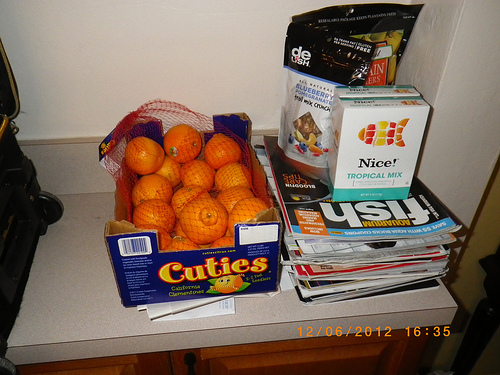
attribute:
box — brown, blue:
[101, 214, 289, 309]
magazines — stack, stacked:
[291, 191, 437, 313]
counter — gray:
[31, 203, 427, 336]